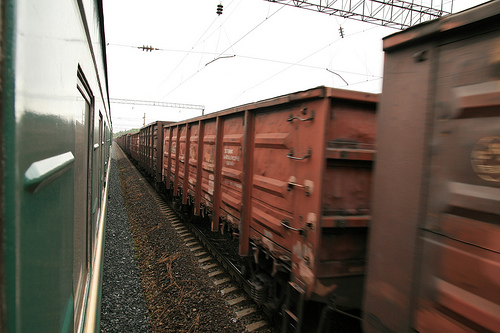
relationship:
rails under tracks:
[108, 143, 267, 332] [119, 151, 315, 327]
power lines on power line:
[111, 0, 389, 96] [13, 31, 292, 69]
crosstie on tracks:
[223, 292, 247, 309] [113, 140, 367, 331]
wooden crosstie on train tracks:
[217, 282, 237, 293] [112, 141, 298, 332]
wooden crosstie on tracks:
[169, 222, 181, 229] [108, 138, 308, 330]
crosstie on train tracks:
[181, 240, 201, 246] [112, 141, 298, 332]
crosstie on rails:
[195, 247, 206, 255] [108, 141, 269, 332]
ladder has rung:
[279, 109, 316, 241] [284, 106, 316, 126]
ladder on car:
[279, 109, 316, 241] [158, 76, 378, 318]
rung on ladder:
[286, 178, 313, 193] [279, 107, 314, 235]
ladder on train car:
[279, 107, 314, 235] [161, 82, 381, 319]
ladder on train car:
[279, 107, 314, 235] [155, 99, 370, 310]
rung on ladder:
[280, 217, 313, 236] [279, 107, 314, 235]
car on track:
[111, 0, 498, 330] [122, 243, 283, 332]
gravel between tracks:
[98, 130, 283, 332] [170, 227, 189, 236]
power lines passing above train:
[111, 0, 389, 96] [115, 62, 359, 312]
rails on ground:
[108, 141, 269, 332] [106, 200, 211, 328]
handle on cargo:
[284, 113, 313, 123] [160, 84, 381, 328]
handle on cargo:
[282, 145, 315, 163] [160, 84, 381, 328]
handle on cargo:
[282, 175, 314, 193] [160, 84, 381, 328]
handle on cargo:
[276, 217, 305, 234] [160, 84, 381, 328]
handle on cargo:
[286, 145, 312, 160] [273, 103, 320, 265]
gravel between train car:
[98, 130, 283, 332] [155, 84, 370, 311]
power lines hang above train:
[122, 0, 374, 90] [113, 0, 499, 330]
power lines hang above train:
[122, 0, 374, 90] [15, 1, 124, 331]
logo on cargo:
[455, 126, 498, 188] [113, 14, 497, 328]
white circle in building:
[107, 135, 120, 166] [90, 84, 157, 162]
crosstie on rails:
[205, 278, 232, 289] [108, 141, 269, 332]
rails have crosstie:
[108, 141, 269, 332] [205, 278, 232, 289]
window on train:
[77, 87, 87, 332] [0, 0, 113, 332]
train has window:
[0, 0, 113, 332] [77, 87, 87, 332]